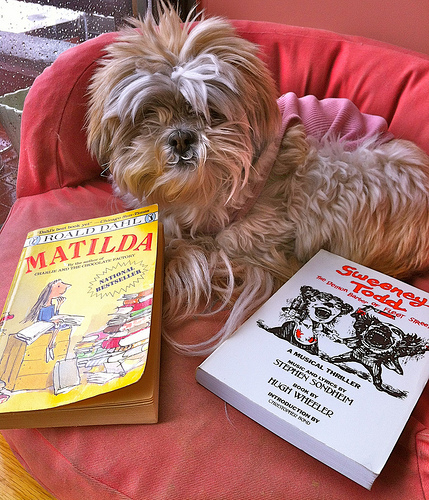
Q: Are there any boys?
A: No, there are no boys.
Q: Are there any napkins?
A: No, there are no napkins.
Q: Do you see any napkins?
A: No, there are no napkins.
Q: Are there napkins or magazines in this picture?
A: No, there are no napkins or magazines.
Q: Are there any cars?
A: No, there are no cars.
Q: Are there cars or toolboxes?
A: No, there are no cars or toolboxes.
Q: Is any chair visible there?
A: Yes, there is a chair.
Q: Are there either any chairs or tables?
A: Yes, there is a chair.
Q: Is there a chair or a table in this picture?
A: Yes, there is a chair.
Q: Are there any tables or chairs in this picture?
A: Yes, there is a chair.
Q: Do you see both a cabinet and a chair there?
A: No, there is a chair but no cabinets.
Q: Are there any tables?
A: No, there are no tables.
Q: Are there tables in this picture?
A: No, there are no tables.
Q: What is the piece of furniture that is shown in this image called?
A: The piece of furniture is a chair.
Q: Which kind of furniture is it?
A: The piece of furniture is a chair.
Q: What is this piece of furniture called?
A: This is a chair.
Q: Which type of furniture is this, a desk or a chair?
A: This is a chair.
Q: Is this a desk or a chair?
A: This is a chair.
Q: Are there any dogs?
A: Yes, there is a dog.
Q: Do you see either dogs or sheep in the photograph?
A: Yes, there is a dog.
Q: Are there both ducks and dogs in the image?
A: No, there is a dog but no ducks.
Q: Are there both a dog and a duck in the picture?
A: No, there is a dog but no ducks.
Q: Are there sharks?
A: No, there are no sharks.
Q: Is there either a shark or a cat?
A: No, there are no sharks or cats.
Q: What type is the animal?
A: The animal is a dog.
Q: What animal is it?
A: The animal is a dog.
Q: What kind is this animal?
A: This is a dog.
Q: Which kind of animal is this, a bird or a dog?
A: This is a dog.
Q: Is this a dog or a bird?
A: This is a dog.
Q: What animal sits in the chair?
A: The dog sits in the chair.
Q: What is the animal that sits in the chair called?
A: The animal is a dog.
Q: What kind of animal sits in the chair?
A: The animal is a dog.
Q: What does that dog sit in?
A: The dog sits in the chair.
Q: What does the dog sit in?
A: The dog sits in the chair.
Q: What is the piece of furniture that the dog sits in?
A: The piece of furniture is a chair.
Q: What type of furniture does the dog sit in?
A: The dog sits in the chair.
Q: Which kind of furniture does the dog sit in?
A: The dog sits in the chair.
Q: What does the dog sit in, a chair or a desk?
A: The dog sits in a chair.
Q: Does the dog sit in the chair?
A: Yes, the dog sits in the chair.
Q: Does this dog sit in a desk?
A: No, the dog sits in the chair.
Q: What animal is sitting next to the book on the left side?
A: The dog is sitting next to the book.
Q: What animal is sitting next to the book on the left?
A: The animal is a dog.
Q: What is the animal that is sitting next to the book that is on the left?
A: The animal is a dog.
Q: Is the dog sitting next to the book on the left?
A: Yes, the dog is sitting next to the book.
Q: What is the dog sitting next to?
A: The dog is sitting next to the book.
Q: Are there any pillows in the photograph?
A: Yes, there is a pillow.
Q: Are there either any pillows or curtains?
A: Yes, there is a pillow.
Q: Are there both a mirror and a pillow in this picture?
A: No, there is a pillow but no mirrors.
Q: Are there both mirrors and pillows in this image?
A: No, there is a pillow but no mirrors.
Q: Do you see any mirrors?
A: No, there are no mirrors.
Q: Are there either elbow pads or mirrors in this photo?
A: No, there are no mirrors or elbow pads.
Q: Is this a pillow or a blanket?
A: This is a pillow.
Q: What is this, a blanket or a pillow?
A: This is a pillow.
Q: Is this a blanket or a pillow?
A: This is a pillow.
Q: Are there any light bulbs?
A: No, there are no light bulbs.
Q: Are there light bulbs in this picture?
A: No, there are no light bulbs.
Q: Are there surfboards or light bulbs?
A: No, there are no light bulbs or surfboards.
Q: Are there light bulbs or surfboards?
A: No, there are no light bulbs or surfboards.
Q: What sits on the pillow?
A: The book sits on the pillow.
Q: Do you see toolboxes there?
A: No, there are no toolboxes.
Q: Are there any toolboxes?
A: No, there are no toolboxes.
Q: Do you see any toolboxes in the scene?
A: No, there are no toolboxes.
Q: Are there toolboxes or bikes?
A: No, there are no toolboxes or bikes.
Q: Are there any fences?
A: No, there are no fences.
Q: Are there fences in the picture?
A: No, there are no fences.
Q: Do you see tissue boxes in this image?
A: No, there are no tissue boxes.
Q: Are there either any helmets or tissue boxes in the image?
A: No, there are no tissue boxes or helmets.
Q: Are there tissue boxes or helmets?
A: No, there are no tissue boxes or helmets.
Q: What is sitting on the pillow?
A: The book is sitting on the pillow.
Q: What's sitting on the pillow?
A: The book is sitting on the pillow.